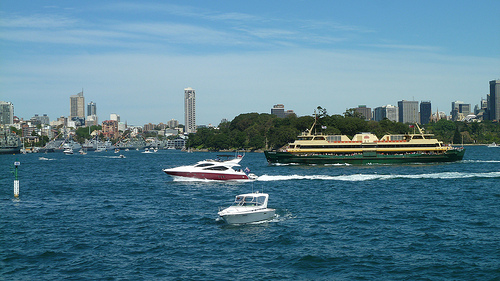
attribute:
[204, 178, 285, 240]
boat — white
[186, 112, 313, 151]
trees — many, green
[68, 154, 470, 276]
water — blue, ocean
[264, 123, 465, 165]
ship — green bottom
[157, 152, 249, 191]
boat — red, white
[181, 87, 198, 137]
white building — tall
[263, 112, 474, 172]
boat — green, tan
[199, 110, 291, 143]
trees — large, green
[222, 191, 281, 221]
boat — white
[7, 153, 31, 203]
object — white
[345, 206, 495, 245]
water — choppy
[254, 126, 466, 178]
boat — large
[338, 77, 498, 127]
buildings — many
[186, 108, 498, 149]
trees — green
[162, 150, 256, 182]
boat — red and white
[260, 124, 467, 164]
boat — red and green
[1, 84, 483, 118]
skyline — city